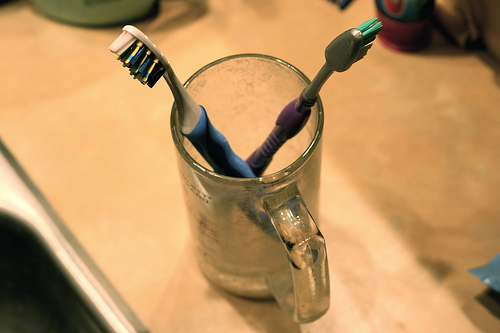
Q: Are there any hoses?
A: No, there are no hoses.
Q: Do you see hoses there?
A: No, there are no hoses.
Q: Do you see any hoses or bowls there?
A: No, there are no hoses or bowls.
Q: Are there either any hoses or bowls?
A: No, there are no hoses or bowls.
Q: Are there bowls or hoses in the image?
A: No, there are no hoses or bowls.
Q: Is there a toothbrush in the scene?
A: Yes, there is a toothbrush.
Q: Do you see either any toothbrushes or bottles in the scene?
A: Yes, there is a toothbrush.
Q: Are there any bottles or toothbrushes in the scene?
A: Yes, there is a toothbrush.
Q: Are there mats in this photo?
A: No, there are no mats.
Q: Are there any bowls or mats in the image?
A: No, there are no mats or bowls.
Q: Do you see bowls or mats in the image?
A: No, there are no mats or bowls.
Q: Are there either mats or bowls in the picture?
A: No, there are no mats or bowls.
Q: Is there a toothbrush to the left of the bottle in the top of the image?
A: Yes, there is a toothbrush to the left of the bottle.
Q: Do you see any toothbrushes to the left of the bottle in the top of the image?
A: Yes, there is a toothbrush to the left of the bottle.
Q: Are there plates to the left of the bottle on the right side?
A: No, there is a toothbrush to the left of the bottle.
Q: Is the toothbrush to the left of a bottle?
A: Yes, the toothbrush is to the left of a bottle.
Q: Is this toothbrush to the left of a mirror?
A: No, the toothbrush is to the left of a bottle.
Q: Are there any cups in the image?
A: Yes, there is a cup.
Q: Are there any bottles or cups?
A: Yes, there is a cup.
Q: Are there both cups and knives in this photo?
A: No, there is a cup but no knives.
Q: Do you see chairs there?
A: No, there are no chairs.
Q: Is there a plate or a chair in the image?
A: No, there are no chairs or plates.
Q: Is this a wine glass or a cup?
A: This is a cup.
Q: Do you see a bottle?
A: Yes, there is a bottle.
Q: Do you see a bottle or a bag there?
A: Yes, there is a bottle.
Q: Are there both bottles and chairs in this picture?
A: No, there is a bottle but no chairs.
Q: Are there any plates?
A: No, there are no plates.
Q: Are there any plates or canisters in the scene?
A: No, there are no plates or canisters.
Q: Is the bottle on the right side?
A: Yes, the bottle is on the right of the image.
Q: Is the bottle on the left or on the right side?
A: The bottle is on the right of the image.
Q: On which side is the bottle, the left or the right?
A: The bottle is on the right of the image.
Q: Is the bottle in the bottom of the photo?
A: No, the bottle is in the top of the image.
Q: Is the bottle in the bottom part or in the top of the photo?
A: The bottle is in the top of the image.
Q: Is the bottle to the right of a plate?
A: No, the bottle is to the right of the toothbrush.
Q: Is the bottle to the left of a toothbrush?
A: No, the bottle is to the right of a toothbrush.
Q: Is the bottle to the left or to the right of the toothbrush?
A: The bottle is to the right of the toothbrush.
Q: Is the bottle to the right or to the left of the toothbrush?
A: The bottle is to the right of the toothbrush.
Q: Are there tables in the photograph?
A: Yes, there is a table.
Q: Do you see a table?
A: Yes, there is a table.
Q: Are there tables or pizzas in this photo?
A: Yes, there is a table.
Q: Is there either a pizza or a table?
A: Yes, there is a table.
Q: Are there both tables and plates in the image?
A: No, there is a table but no plates.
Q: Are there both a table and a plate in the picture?
A: No, there is a table but no plates.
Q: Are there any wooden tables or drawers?
A: Yes, there is a wood table.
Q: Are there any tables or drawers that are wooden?
A: Yes, the table is wooden.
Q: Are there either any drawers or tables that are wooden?
A: Yes, the table is wooden.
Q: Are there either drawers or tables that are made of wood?
A: Yes, the table is made of wood.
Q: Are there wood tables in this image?
A: Yes, there is a wood table.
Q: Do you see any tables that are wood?
A: Yes, there is a wood table.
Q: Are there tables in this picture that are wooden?
A: Yes, there is a table that is wooden.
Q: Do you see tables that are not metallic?
A: Yes, there is a wooden table.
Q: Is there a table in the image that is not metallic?
A: Yes, there is a wooden table.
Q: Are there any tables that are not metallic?
A: Yes, there is a wooden table.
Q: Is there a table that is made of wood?
A: Yes, there is a table that is made of wood.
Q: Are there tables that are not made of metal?
A: Yes, there is a table that is made of wood.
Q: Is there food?
A: No, there is no food.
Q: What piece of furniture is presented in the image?
A: The piece of furniture is a table.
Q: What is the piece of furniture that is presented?
A: The piece of furniture is a table.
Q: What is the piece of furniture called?
A: The piece of furniture is a table.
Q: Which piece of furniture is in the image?
A: The piece of furniture is a table.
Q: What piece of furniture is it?
A: The piece of furniture is a table.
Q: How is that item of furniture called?
A: This is a table.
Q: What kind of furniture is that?
A: This is a table.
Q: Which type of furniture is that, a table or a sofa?
A: This is a table.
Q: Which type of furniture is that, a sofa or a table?
A: This is a table.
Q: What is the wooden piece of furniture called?
A: The piece of furniture is a table.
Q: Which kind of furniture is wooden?
A: The furniture is a table.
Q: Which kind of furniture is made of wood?
A: The furniture is a table.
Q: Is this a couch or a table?
A: This is a table.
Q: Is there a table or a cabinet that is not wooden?
A: No, there is a table but it is wooden.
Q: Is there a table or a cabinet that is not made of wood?
A: No, there is a table but it is made of wood.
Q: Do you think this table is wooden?
A: Yes, the table is wooden.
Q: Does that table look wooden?
A: Yes, the table is wooden.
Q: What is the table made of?
A: The table is made of wood.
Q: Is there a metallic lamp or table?
A: No, there is a table but it is wooden.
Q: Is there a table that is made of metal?
A: No, there is a table but it is made of wood.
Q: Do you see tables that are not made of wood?
A: No, there is a table but it is made of wood.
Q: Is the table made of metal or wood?
A: The table is made of wood.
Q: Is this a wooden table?
A: Yes, this is a wooden table.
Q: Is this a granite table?
A: No, this is a wooden table.